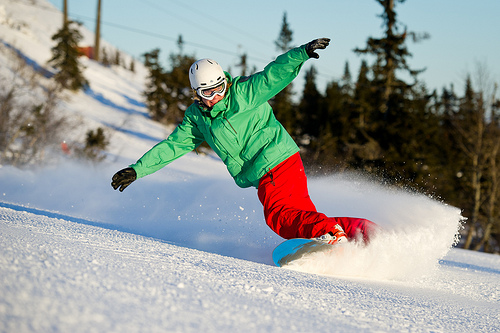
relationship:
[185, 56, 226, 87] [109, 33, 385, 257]
helmet on person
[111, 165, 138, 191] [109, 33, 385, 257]
glove on person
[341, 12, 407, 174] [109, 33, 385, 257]
tree behind person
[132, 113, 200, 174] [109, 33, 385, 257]
arm on person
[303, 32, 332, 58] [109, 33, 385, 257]
hand of person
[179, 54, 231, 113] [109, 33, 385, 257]
head of person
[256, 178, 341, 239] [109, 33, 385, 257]
leg of person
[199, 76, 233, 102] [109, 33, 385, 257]
goggles on person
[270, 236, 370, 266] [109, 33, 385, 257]
snowboard under person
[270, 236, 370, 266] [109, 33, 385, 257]
snowboard on person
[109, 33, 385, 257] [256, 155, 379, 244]
person in pants